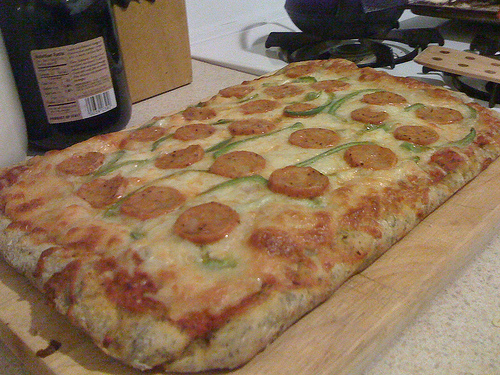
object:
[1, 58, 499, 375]
pizza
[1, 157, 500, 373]
board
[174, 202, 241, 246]
pepperoni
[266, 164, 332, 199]
pepperoni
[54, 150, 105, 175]
pepperoni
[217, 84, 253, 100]
pepperoni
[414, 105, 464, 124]
pepperoni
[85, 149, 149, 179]
green pepper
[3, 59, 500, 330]
cheese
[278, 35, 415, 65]
fire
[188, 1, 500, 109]
oven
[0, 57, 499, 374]
counter top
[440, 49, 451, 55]
hole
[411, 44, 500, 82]
spatula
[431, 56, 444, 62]
hole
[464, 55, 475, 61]
hole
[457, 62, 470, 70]
hole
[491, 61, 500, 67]
hole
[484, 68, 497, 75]
hole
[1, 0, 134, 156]
bottle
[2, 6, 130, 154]
liquid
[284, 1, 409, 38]
pan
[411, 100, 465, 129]
meat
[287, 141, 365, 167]
green peppers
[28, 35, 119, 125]
label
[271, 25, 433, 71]
burner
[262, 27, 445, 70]
grate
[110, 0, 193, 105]
block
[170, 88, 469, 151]
range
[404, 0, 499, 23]
tray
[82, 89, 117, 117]
bar code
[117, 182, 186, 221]
meat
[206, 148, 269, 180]
meat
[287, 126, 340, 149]
meat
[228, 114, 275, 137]
meat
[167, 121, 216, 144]
meat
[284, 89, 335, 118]
pepper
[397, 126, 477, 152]
pepper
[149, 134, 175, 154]
pepper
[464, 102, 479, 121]
pepper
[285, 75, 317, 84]
pepper